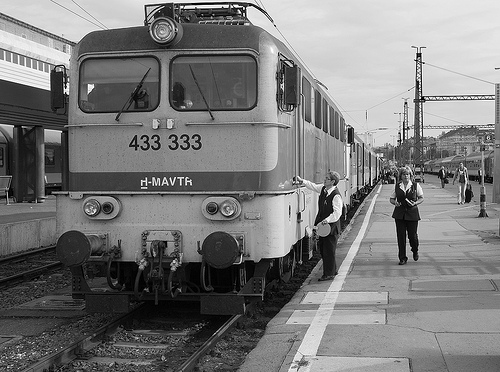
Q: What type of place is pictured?
A: It is a sidewalk.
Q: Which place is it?
A: It is a sidewalk.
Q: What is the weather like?
A: It is cloudy.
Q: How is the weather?
A: It is cloudy.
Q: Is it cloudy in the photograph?
A: Yes, it is cloudy.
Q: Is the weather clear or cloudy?
A: It is cloudy.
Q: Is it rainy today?
A: No, it is cloudy.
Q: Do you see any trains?
A: Yes, there is a train.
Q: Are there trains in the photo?
A: Yes, there is a train.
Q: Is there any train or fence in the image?
A: Yes, there is a train.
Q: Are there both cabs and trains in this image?
A: No, there is a train but no taxis.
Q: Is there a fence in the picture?
A: No, there are no fences.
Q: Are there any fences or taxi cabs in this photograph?
A: No, there are no fences or taxi cabs.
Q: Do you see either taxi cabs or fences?
A: No, there are no fences or taxi cabs.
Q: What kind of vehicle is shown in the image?
A: The vehicle is a train.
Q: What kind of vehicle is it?
A: The vehicle is a train.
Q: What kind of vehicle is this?
A: This is a train.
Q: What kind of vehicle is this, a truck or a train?
A: This is a train.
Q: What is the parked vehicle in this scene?
A: The vehicle is a train.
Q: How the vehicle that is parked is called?
A: The vehicle is a train.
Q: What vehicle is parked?
A: The vehicle is a train.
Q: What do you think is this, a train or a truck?
A: This is a train.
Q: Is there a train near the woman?
A: Yes, there is a train near the woman.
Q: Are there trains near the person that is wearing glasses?
A: Yes, there is a train near the woman.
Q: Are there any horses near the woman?
A: No, there is a train near the woman.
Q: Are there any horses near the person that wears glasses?
A: No, there is a train near the woman.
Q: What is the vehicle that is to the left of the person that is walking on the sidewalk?
A: The vehicle is a train.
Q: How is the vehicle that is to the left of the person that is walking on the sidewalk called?
A: The vehicle is a train.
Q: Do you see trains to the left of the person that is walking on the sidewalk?
A: Yes, there is a train to the left of the person.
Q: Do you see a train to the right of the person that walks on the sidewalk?
A: No, the train is to the left of the person.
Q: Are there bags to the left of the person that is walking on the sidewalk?
A: No, there is a train to the left of the person.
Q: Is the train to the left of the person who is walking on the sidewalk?
A: Yes, the train is to the left of the person.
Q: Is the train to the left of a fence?
A: No, the train is to the left of the person.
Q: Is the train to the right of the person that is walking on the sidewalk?
A: No, the train is to the left of the person.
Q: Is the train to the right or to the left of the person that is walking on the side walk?
A: The train is to the left of the person.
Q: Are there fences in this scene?
A: No, there are no fences.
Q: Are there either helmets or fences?
A: No, there are no fences or helmets.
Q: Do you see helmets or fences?
A: No, there are no fences or helmets.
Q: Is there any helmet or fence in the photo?
A: No, there are no fences or helmets.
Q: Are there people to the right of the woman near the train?
A: Yes, there is a person to the right of the woman.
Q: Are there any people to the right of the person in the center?
A: Yes, there is a person to the right of the woman.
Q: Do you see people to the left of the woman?
A: No, the person is to the right of the woman.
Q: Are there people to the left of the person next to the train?
A: No, the person is to the right of the woman.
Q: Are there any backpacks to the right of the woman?
A: No, there is a person to the right of the woman.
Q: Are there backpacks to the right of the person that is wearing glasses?
A: No, there is a person to the right of the woman.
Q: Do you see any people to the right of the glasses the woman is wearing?
A: Yes, there is a person to the right of the glasses.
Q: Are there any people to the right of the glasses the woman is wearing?
A: Yes, there is a person to the right of the glasses.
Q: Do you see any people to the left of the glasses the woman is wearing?
A: No, the person is to the right of the glasses.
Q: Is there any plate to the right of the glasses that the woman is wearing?
A: No, there is a person to the right of the glasses.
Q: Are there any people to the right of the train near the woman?
A: Yes, there is a person to the right of the train.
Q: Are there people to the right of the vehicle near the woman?
A: Yes, there is a person to the right of the train.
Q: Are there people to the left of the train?
A: No, the person is to the right of the train.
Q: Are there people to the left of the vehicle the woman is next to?
A: No, the person is to the right of the train.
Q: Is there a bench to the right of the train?
A: No, there is a person to the right of the train.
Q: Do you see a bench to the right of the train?
A: No, there is a person to the right of the train.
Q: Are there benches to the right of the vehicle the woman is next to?
A: No, there is a person to the right of the train.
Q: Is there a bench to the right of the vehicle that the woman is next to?
A: No, there is a person to the right of the train.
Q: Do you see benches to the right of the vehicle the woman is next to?
A: No, there is a person to the right of the train.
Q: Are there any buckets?
A: No, there are no buckets.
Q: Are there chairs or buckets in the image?
A: No, there are no buckets or chairs.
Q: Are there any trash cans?
A: No, there are no trash cans.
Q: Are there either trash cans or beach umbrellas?
A: No, there are no trash cans or beach umbrellas.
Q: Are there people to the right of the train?
A: Yes, there is a person to the right of the train.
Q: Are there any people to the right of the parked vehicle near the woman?
A: Yes, there is a person to the right of the train.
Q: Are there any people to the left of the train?
A: No, the person is to the right of the train.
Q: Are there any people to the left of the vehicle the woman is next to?
A: No, the person is to the right of the train.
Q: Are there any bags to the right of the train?
A: No, there is a person to the right of the train.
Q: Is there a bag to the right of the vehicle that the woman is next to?
A: No, there is a person to the right of the train.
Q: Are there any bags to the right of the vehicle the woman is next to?
A: No, there is a person to the right of the train.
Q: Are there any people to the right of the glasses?
A: Yes, there is a person to the right of the glasses.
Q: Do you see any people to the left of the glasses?
A: No, the person is to the right of the glasses.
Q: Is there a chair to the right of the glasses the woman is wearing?
A: No, there is a person to the right of the glasses.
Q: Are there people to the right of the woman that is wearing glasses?
A: Yes, there is a person to the right of the woman.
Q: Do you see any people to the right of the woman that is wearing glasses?
A: Yes, there is a person to the right of the woman.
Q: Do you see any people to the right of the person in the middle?
A: Yes, there is a person to the right of the woman.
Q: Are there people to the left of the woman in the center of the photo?
A: No, the person is to the right of the woman.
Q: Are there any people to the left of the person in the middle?
A: No, the person is to the right of the woman.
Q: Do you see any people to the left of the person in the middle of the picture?
A: No, the person is to the right of the woman.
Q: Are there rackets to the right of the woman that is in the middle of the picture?
A: No, there is a person to the right of the woman.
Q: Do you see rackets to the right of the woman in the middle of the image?
A: No, there is a person to the right of the woman.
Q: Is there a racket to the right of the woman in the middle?
A: No, there is a person to the right of the woman.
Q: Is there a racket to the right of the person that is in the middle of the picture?
A: No, there is a person to the right of the woman.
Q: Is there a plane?
A: No, there are no airplanes.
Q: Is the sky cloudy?
A: Yes, the sky is cloudy.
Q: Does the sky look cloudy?
A: Yes, the sky is cloudy.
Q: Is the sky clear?
A: No, the sky is cloudy.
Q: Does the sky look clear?
A: No, the sky is cloudy.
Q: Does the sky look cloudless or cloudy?
A: The sky is cloudy.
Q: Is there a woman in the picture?
A: Yes, there is a woman.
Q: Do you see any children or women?
A: Yes, there is a woman.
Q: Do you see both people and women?
A: Yes, there are both a woman and a person.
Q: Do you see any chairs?
A: No, there are no chairs.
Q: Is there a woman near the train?
A: Yes, there is a woman near the train.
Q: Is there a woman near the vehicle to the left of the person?
A: Yes, there is a woman near the train.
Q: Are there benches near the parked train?
A: No, there is a woman near the train.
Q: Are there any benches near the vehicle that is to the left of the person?
A: No, there is a woman near the train.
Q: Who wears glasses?
A: The woman wears glasses.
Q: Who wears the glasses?
A: The woman wears glasses.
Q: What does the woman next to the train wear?
A: The woman wears glasses.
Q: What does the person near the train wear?
A: The woman wears glasses.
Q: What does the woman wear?
A: The woman wears glasses.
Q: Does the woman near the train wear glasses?
A: Yes, the woman wears glasses.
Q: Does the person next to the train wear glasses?
A: Yes, the woman wears glasses.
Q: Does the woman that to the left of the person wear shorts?
A: No, the woman wears glasses.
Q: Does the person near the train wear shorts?
A: No, the woman wears glasses.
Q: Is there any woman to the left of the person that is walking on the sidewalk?
A: Yes, there is a woman to the left of the person.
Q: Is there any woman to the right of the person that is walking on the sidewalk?
A: No, the woman is to the left of the person.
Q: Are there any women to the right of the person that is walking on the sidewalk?
A: No, the woman is to the left of the person.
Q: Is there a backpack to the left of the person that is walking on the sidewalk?
A: No, there is a woman to the left of the person.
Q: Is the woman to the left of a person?
A: Yes, the woman is to the left of a person.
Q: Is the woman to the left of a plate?
A: No, the woman is to the left of a person.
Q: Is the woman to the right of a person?
A: No, the woman is to the left of a person.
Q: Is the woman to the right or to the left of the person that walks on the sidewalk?
A: The woman is to the left of the person.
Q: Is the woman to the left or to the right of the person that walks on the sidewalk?
A: The woman is to the left of the person.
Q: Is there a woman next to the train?
A: Yes, there is a woman next to the train.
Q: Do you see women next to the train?
A: Yes, there is a woman next to the train.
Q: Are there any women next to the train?
A: Yes, there is a woman next to the train.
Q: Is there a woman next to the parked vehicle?
A: Yes, there is a woman next to the train.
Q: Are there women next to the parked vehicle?
A: Yes, there is a woman next to the train.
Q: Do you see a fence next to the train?
A: No, there is a woman next to the train.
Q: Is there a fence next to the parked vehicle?
A: No, there is a woman next to the train.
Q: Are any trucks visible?
A: No, there are no trucks.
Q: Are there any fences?
A: No, there are no fences.